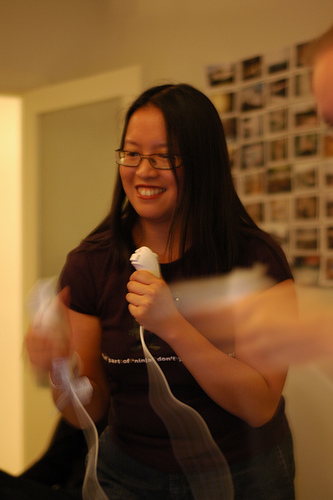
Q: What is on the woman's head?
A: Glasses.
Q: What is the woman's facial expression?
A: She is smiling.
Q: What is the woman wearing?
A: A black shirt.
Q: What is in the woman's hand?
A: A wii controller.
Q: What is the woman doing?
A: Playing a video game.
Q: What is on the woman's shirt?
A: A bunch of letters.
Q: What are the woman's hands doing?
A: Moving the game controller.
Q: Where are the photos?
A: On wall.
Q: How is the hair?
A: Dark.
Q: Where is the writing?
A: On shirt.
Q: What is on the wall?
A: Pictures.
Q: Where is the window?
A: On door.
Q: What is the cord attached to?
A: Controllers.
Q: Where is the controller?
A: In hand.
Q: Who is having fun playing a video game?
A: A girl.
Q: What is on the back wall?
A: A picture collection.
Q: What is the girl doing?
A: Playing video games.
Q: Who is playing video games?
A: The girl.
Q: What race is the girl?
A: Asian.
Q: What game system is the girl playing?
A: Nintendo Wii.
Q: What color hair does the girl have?
A: Black.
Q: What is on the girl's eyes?
A: Glasses.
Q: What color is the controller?
A: White.